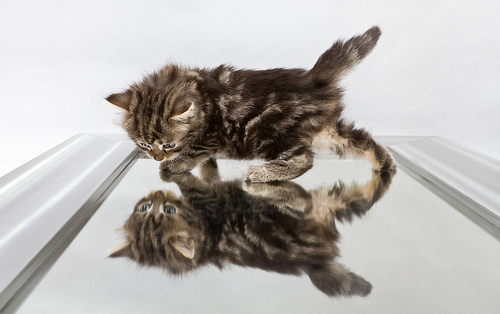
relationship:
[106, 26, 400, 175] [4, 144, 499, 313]
cat on mirror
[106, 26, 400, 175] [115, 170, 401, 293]
cat has reflection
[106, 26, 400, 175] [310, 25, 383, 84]
cat has tail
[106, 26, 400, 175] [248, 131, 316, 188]
cat has leg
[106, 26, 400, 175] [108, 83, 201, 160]
cat has head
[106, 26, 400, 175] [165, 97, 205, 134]
cat has ear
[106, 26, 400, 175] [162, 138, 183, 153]
cat has eye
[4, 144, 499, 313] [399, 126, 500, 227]
mirror has edge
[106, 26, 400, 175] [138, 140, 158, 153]
cat has eye